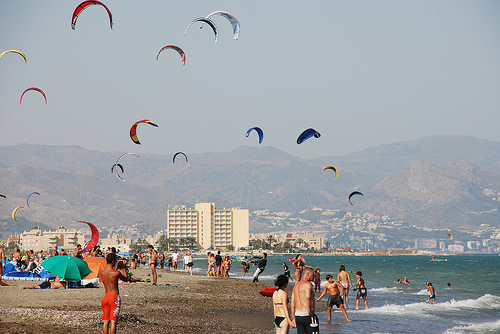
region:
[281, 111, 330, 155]
a blue kite in the air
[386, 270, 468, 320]
several people in the water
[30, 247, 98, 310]
a green umbrella on the beach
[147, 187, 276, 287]
a building in the background at the beach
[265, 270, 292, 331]
a woman in a black bikini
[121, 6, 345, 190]
several kites of different colors in the air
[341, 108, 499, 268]
a mountain near water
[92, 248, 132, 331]
a male with orange swim trunks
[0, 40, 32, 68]
a yellow kite in the sky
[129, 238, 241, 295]
many people on a beach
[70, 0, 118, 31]
A red kite in the air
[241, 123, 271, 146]
A blue kite in the sky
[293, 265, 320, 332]
A man in black shorts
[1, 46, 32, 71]
A yellow kite in the air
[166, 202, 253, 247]
A white building in the background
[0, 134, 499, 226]
Large mountains in the distance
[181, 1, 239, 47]
Two kites in the air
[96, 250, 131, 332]
A man in red shorts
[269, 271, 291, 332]
A woman in a black bikini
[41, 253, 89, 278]
A green umbrella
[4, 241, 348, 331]
many tourists having fun on a beach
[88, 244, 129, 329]
a man in swimming trunks taking a photo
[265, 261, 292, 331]
a young woman in a black bikini holding hands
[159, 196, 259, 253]
a tall white hotel near a busy beach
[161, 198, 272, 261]
a large expensive hotel standing beneath a mountain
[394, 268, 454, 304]
happy people splashing around in the ocean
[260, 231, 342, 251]
a little city sitting next to a beach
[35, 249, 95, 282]
a large green umbrella shading a man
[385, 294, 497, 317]
frothy white waves in a blue sea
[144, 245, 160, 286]
a man in burgundy speedos looking down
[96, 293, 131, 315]
the shorts are red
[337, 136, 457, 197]
their are hills in the background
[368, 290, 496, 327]
there are small waves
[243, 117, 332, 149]
the kite is blue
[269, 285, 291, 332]
woman in swimsuit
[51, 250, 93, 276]
umbrella is blue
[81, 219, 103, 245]
the kite is red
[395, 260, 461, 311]
the people are in the water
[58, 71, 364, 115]
the sky is dull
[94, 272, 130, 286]
the person is shirtless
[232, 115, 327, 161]
two blue kites in the sky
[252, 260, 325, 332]
man and woman holding hands on the beach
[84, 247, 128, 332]
man in red swim trunks on the beach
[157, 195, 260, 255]
large beige building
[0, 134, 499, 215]
mountain range in the distance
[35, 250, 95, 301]
green umbrella on the beach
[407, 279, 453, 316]
person in the ocean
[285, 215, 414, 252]
buildings on the hillside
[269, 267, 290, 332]
woman in black bikini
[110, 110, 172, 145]
multi-colored kite